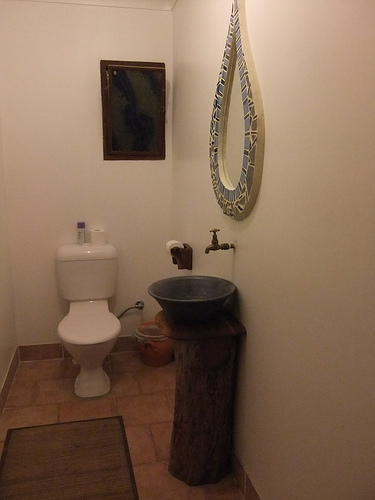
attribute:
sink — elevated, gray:
[141, 268, 240, 331]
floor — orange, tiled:
[33, 342, 194, 499]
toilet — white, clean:
[47, 247, 138, 412]